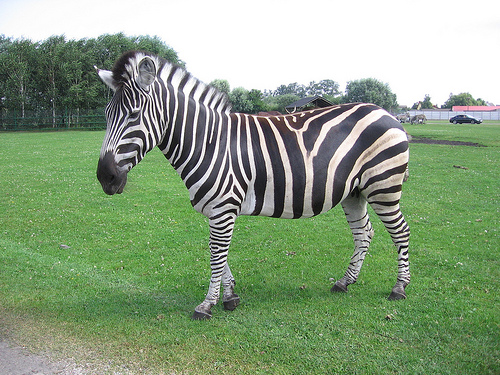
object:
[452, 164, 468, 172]
excrement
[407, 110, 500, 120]
wall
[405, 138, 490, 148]
soil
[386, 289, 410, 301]
hoof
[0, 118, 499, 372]
ground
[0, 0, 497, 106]
sky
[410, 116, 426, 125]
elephants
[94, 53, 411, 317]
zebra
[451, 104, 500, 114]
roof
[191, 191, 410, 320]
four legs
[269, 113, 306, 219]
stripes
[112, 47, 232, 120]
mane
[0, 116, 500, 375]
grass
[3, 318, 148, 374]
path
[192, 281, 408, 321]
four hooves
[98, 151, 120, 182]
black nose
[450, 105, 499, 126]
building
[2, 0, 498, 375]
background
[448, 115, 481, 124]
car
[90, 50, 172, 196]
large head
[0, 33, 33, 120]
trees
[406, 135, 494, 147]
ditch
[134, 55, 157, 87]
ears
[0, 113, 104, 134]
fence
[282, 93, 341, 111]
black roof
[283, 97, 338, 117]
building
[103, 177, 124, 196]
mouth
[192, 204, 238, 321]
front left leg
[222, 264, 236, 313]
right leg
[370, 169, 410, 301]
back left leg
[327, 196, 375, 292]
back right leg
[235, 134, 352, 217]
stomach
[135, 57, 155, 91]
left ear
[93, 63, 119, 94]
right ear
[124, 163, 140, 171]
eye